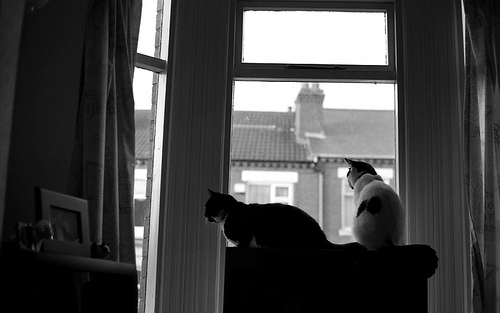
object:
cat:
[343, 155, 406, 251]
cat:
[203, 186, 365, 250]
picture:
[53, 207, 84, 243]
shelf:
[7, 250, 135, 310]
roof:
[233, 106, 396, 163]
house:
[233, 82, 403, 246]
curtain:
[82, 2, 138, 262]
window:
[123, 4, 167, 306]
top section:
[138, 0, 172, 55]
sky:
[241, 13, 394, 112]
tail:
[386, 241, 437, 254]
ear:
[342, 157, 354, 168]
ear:
[206, 188, 218, 196]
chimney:
[295, 83, 325, 142]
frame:
[39, 186, 91, 256]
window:
[273, 187, 289, 198]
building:
[232, 83, 394, 245]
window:
[233, 7, 402, 257]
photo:
[5, 4, 494, 311]